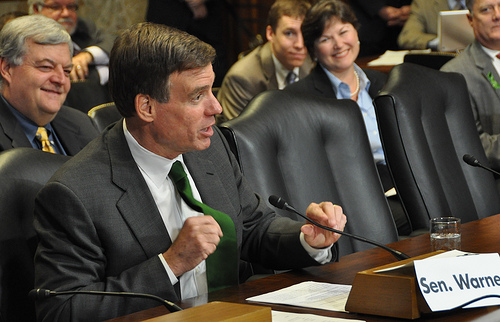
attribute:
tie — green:
[164, 159, 250, 288]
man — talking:
[28, 18, 353, 322]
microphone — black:
[267, 189, 414, 264]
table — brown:
[63, 205, 497, 321]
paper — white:
[242, 275, 376, 321]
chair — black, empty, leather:
[220, 85, 412, 258]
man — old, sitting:
[2, 11, 102, 158]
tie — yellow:
[34, 125, 57, 155]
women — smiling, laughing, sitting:
[285, 4, 429, 239]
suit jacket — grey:
[217, 40, 339, 128]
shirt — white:
[123, 127, 216, 305]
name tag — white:
[411, 254, 499, 314]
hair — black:
[108, 20, 220, 109]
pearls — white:
[334, 69, 365, 100]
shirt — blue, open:
[317, 61, 395, 170]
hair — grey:
[2, 12, 83, 69]